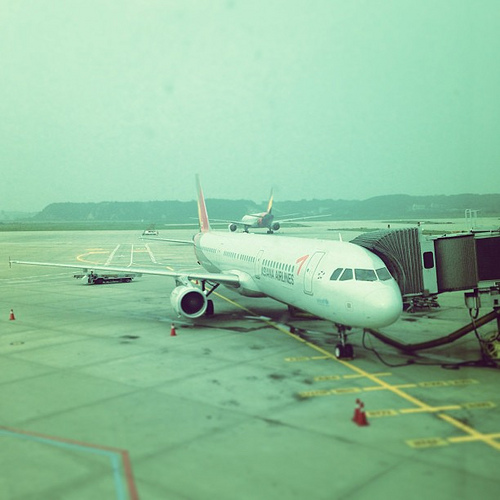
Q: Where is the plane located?
A: Airport.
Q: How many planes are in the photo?
A: Two.